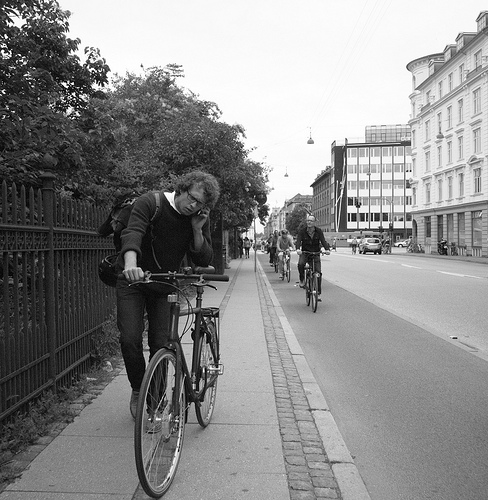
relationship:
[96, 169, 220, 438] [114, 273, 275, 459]
man walking h bike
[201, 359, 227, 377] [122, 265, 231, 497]
foot pedal of bike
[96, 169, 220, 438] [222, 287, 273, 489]
man on sidewalk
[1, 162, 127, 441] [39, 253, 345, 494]
metal fence beside sidewalk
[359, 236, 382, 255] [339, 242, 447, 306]
car parked sidewalk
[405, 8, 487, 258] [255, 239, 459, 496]
building alongside road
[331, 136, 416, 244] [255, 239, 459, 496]
building alongside road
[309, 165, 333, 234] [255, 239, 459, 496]
building alongside road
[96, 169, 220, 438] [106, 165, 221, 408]
man talking on phone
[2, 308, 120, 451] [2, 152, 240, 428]
weeds at bottom of fence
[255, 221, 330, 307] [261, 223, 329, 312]
row of bikers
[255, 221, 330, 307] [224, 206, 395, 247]
row in distance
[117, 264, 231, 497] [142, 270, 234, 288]
bicycle has bars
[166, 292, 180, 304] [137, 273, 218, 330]
reflector on front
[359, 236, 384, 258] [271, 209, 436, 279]
car in distance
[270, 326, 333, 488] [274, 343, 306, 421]
row of bricks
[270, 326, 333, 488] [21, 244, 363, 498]
row on sidewalk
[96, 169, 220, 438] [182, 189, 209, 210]
man wearing glasses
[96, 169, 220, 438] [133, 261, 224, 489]
man has bike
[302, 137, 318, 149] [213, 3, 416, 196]
object on wires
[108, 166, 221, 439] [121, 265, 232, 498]
man on bicycle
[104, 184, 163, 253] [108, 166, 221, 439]
back pack on man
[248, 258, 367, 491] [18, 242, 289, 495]
curb on sidewalk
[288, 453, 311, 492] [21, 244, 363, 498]
brick area on sidewalk